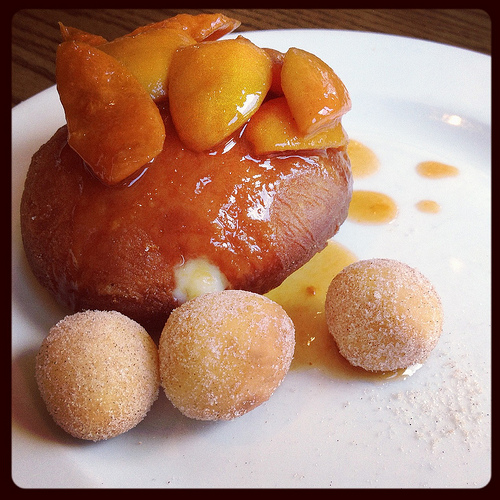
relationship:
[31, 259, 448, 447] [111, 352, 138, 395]
doughnuts have sprinkles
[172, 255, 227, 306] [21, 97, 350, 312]
stuff moving out of dough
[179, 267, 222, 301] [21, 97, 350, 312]
stuff moving out of dough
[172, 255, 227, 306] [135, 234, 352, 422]
stuff moving out of dough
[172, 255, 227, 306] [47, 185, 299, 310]
stuff moving out of dough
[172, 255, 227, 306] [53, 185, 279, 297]
stuff moving out of dough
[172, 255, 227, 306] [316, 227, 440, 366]
stuff moving out of dough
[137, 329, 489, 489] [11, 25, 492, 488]
sugar crystals on plate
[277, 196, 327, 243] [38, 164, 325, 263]
skin on potato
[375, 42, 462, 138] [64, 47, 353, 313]
plate holding food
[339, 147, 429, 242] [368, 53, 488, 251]
sauce dripping on plate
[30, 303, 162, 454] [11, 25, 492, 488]
food on plate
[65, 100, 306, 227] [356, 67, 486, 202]
brown syrup on plate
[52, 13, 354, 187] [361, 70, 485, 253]
peaches on plate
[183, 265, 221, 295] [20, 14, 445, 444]
cream inside food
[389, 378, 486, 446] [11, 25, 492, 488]
sugar on plate